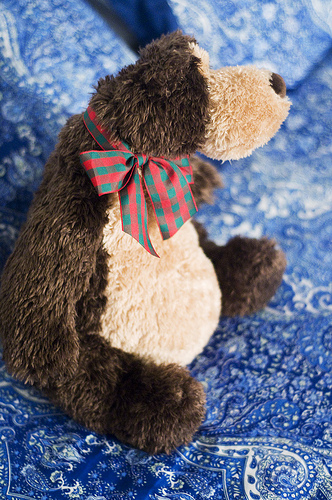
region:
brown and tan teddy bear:
[0, 27, 292, 451]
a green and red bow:
[82, 109, 201, 256]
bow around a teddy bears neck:
[81, 108, 198, 255]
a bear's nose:
[270, 68, 289, 96]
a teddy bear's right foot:
[121, 357, 208, 458]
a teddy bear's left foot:
[212, 238, 285, 317]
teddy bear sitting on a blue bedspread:
[2, 2, 326, 497]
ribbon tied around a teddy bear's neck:
[84, 108, 201, 256]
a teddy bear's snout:
[207, 64, 291, 161]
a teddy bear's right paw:
[0, 303, 76, 389]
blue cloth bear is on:
[232, 364, 321, 471]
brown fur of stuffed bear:
[96, 371, 157, 420]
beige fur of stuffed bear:
[106, 260, 214, 338]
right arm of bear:
[5, 292, 90, 389]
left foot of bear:
[218, 239, 317, 319]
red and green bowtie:
[85, 145, 144, 223]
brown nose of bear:
[256, 59, 289, 90]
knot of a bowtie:
[126, 147, 155, 173]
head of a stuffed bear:
[100, 45, 306, 163]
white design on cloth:
[244, 467, 266, 496]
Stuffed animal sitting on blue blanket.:
[39, 414, 206, 494]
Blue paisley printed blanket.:
[243, 414, 293, 490]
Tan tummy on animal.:
[133, 240, 203, 326]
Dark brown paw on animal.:
[24, 318, 67, 373]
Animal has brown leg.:
[102, 364, 191, 460]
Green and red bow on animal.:
[93, 110, 190, 216]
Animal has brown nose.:
[270, 70, 293, 101]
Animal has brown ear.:
[143, 47, 208, 107]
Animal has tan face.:
[218, 92, 259, 147]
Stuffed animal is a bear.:
[72, 36, 281, 342]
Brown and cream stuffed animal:
[0, 33, 307, 460]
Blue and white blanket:
[219, 362, 329, 496]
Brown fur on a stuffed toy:
[78, 374, 208, 453]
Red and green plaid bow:
[80, 145, 202, 252]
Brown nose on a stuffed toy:
[259, 68, 294, 110]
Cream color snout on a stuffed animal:
[182, 55, 292, 168]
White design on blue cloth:
[205, 434, 331, 498]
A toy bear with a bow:
[6, 34, 288, 455]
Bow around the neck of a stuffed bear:
[66, 32, 287, 259]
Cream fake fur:
[128, 261, 205, 343]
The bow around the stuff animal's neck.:
[88, 143, 198, 251]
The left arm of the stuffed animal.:
[9, 289, 83, 390]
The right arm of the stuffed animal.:
[199, 159, 221, 205]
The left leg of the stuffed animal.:
[67, 360, 198, 456]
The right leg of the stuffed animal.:
[210, 238, 290, 326]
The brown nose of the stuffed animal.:
[271, 72, 283, 94]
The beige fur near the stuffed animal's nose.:
[211, 64, 285, 156]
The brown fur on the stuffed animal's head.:
[94, 31, 209, 150]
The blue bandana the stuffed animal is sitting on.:
[7, 100, 315, 493]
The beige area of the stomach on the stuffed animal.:
[108, 228, 220, 372]